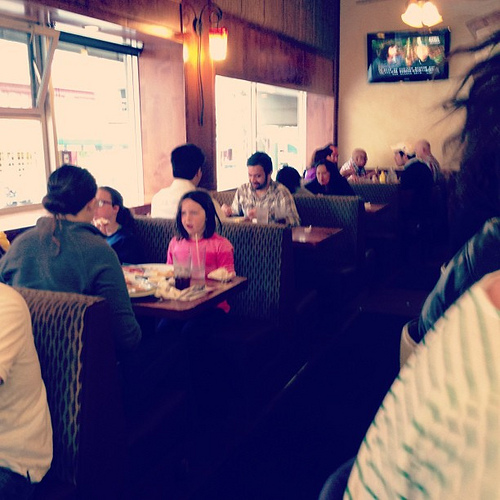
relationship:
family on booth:
[6, 167, 251, 316] [6, 215, 291, 335]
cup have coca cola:
[175, 247, 191, 290] [176, 274, 189, 290]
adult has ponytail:
[0, 163, 140, 353] [41, 162, 95, 254]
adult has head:
[1, 156, 136, 298] [36, 162, 105, 225]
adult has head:
[150, 140, 223, 219] [173, 141, 210, 187]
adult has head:
[304, 155, 357, 204] [315, 162, 337, 186]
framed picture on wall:
[363, 24, 453, 85] [335, 1, 499, 173]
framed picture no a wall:
[366, 29, 449, 83] [335, 1, 499, 173]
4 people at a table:
[306, 142, 374, 194] [337, 165, 419, 188]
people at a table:
[394, 130, 444, 199] [337, 165, 419, 188]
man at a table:
[340, 147, 378, 181] [337, 165, 419, 188]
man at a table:
[394, 139, 430, 211] [337, 165, 419, 188]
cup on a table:
[253, 205, 268, 227] [282, 222, 343, 247]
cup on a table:
[188, 257, 207, 285] [282, 222, 343, 247]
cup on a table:
[167, 251, 191, 290] [128, 262, 251, 316]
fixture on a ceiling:
[399, 0, 446, 28] [261, 0, 488, 5]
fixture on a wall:
[175, 1, 227, 130] [0, 2, 498, 212]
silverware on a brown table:
[173, 281, 205, 302] [120, 264, 246, 318]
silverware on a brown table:
[173, 281, 193, 302] [120, 264, 246, 318]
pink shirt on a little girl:
[163, 232, 236, 277] [163, 185, 238, 337]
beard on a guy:
[249, 176, 269, 192] [221, 149, 301, 228]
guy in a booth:
[221, 149, 301, 228] [144, 182, 378, 352]